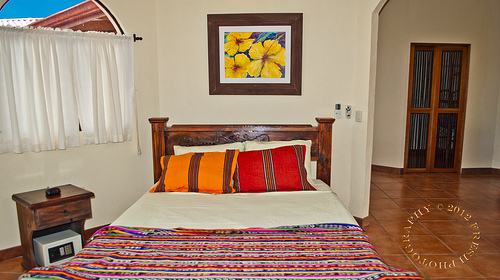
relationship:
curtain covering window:
[0, 24, 138, 157] [4, 2, 129, 30]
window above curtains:
[0, 0, 121, 33] [1, 23, 135, 153]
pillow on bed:
[157, 151, 238, 194] [22, 115, 413, 277]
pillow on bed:
[226, 145, 317, 193] [22, 115, 413, 277]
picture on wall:
[203, 10, 305, 99] [154, 1, 351, 214]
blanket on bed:
[16, 223, 421, 278] [22, 115, 413, 277]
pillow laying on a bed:
[226, 145, 317, 193] [59, 115, 394, 277]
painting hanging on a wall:
[204, 10, 304, 94] [156, 8, 207, 108]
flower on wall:
[247, 38, 284, 77] [154, 1, 351, 214]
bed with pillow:
[22, 115, 413, 277] [152, 149, 237, 193]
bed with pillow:
[22, 115, 413, 277] [233, 143, 319, 192]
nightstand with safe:
[8, 182, 95, 270] [28, 227, 83, 264]